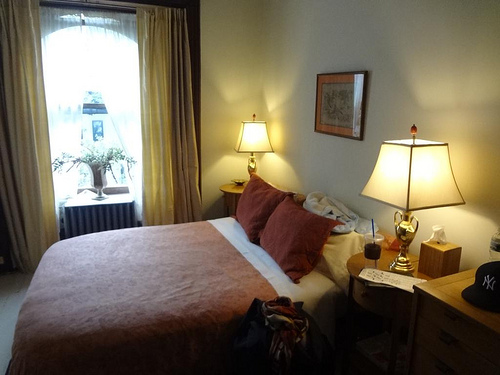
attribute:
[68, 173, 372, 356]
bed — made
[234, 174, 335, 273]
pillows — brown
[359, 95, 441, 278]
lamp — on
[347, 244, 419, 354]
table — wooden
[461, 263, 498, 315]
cap — black